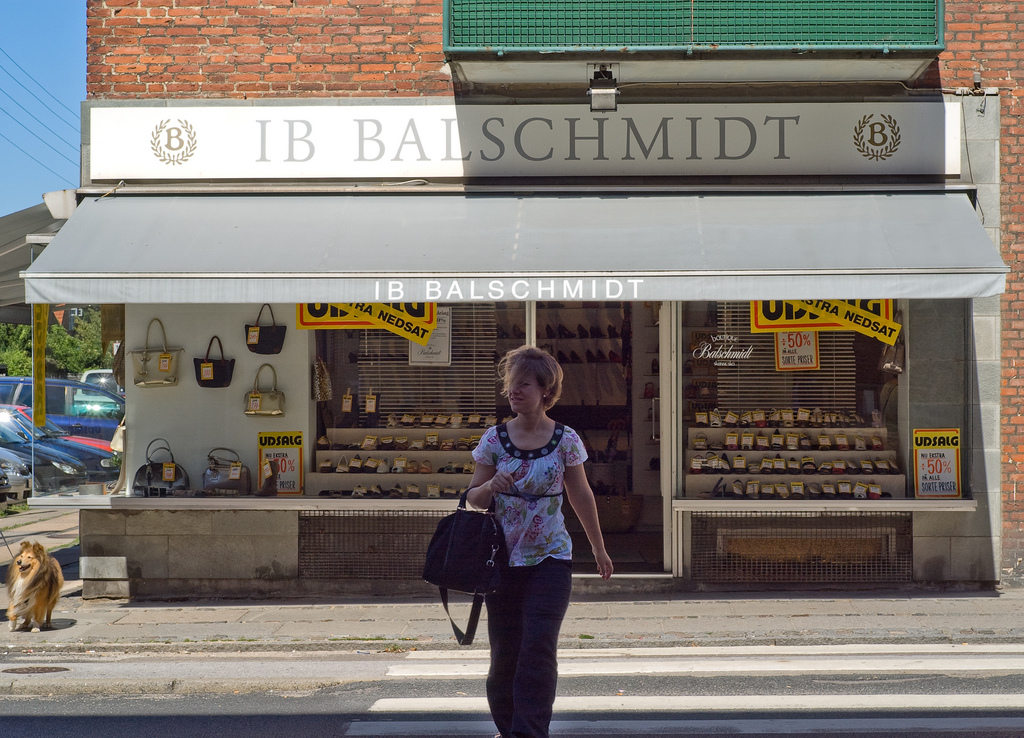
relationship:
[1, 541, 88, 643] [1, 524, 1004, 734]
dog on sidewalk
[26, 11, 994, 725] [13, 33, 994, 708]
picture is taken outdoors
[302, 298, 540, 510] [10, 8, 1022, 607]
wall on side of building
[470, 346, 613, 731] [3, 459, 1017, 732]
lady walking across street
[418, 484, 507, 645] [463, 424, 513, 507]
bag on lady's arm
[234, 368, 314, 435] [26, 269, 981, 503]
bag hanging on display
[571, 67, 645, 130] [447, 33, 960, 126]
light above awning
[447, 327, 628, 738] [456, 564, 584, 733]
lady wearing pants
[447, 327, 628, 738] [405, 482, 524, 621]
lady carrying bag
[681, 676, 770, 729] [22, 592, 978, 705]
lines in street